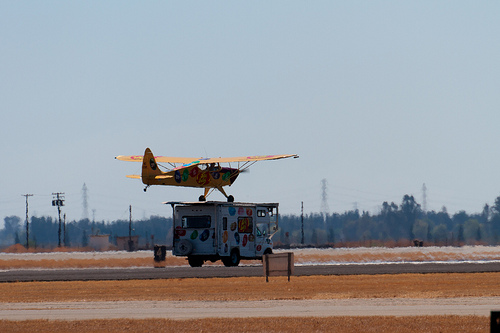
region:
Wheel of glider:
[198, 195, 205, 201]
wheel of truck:
[229, 247, 239, 264]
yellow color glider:
[115, 150, 296, 200]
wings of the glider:
[112, 150, 293, 160]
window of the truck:
[177, 215, 207, 225]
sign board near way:
[261, 251, 291, 276]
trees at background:
[315, 211, 406, 236]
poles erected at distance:
[50, 190, 60, 245]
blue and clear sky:
[91, 30, 451, 127]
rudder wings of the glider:
[140, 147, 157, 180]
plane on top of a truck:
[110, 138, 308, 280]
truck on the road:
[151, 193, 299, 276]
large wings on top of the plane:
[110, 143, 315, 170]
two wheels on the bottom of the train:
[186, 185, 237, 203]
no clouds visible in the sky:
[0, 1, 495, 226]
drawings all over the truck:
[168, 201, 275, 263]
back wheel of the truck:
[220, 243, 242, 264]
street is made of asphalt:
[1, 247, 498, 280]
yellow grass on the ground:
[0, 273, 499, 305]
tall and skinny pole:
[19, 192, 37, 247]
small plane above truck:
[122, 129, 252, 176]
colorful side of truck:
[169, 205, 261, 265]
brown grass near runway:
[143, 274, 410, 296]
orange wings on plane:
[122, 146, 267, 164]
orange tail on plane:
[135, 145, 164, 187]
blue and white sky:
[288, 30, 460, 160]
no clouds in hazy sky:
[356, 77, 494, 211]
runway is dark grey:
[326, 251, 499, 296]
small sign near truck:
[255, 252, 311, 282]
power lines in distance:
[45, 162, 460, 242]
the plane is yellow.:
[110, 139, 302, 206]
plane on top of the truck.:
[106, 139, 296, 267]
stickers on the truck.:
[166, 194, 283, 274]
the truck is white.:
[166, 194, 286, 269]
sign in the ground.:
[258, 247, 303, 284]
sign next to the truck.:
[255, 246, 300, 282]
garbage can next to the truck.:
[146, 239, 169, 271]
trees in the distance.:
[3, 193, 498, 245]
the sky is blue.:
[1, 0, 498, 210]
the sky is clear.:
[1, 1, 498, 213]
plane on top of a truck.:
[111, 133, 288, 269]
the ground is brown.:
[2, 267, 496, 330]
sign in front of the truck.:
[255, 247, 300, 283]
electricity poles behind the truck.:
[17, 185, 139, 250]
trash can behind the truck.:
[150, 239, 167, 261]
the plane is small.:
[107, 130, 302, 210]